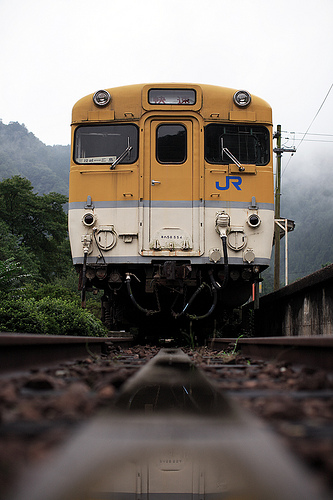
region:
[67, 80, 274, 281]
This is train car in Asia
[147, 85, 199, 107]
The sign is in Asian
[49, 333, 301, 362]
A set of railroad tracks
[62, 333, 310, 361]
The tracks are made of iron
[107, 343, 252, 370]
There is gravel between the rocks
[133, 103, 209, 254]
A door on the train car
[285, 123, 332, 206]
It is foggy in the mountains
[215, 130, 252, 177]
The windshield wiper on the window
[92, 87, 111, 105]
A light on the train car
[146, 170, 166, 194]
The handle on the door of the train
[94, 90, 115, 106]
The left headlight on the train.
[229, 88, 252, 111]
The right headlight of the train.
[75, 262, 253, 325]
The wires and tubes on the front of the train.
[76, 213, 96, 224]
The small black light on the left of the front of the train.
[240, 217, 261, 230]
The right small black light on the front of the train.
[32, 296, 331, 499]
The tracks in front of the train.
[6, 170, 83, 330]
The trees on the left of the train.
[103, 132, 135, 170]
The left windshield wiper on the window of the train.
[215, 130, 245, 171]
The right windshield wiper on the window of the train.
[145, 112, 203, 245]
The door on the front of the train.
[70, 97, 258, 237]
yellow and white school bus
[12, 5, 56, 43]
white clouds in blue sky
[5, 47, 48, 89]
white clouds in blue sky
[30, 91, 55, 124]
white clouds in blue sky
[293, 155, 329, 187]
white clouds in blue sky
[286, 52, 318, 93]
white clouds in blue sky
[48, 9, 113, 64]
white clouds in blue sky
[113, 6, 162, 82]
white clouds in blue sky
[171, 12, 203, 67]
white clouds in blue sky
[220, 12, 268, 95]
white clouds in blue sky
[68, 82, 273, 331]
Train traveling down tracks.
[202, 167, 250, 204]
two blue letters j and r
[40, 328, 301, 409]
rocks on a railroad track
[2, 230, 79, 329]
green treesand bushes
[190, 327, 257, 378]
grass growing on track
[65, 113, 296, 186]
three windows of a train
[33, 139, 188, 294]
yellow gray and white train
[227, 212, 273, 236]
small black light on train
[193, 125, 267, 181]
windshield wiper on window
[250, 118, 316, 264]
telephone lines and pole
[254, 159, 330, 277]
mist around a green tree